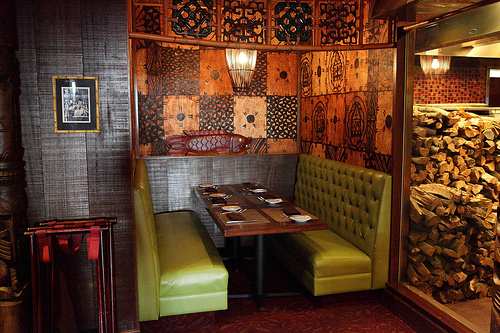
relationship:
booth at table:
[127, 154, 392, 321] [194, 181, 327, 313]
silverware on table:
[216, 214, 251, 224] [194, 181, 327, 313]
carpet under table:
[143, 293, 444, 331] [194, 181, 327, 313]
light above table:
[226, 46, 258, 93] [190, 182, 330, 313]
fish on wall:
[165, 129, 252, 157] [134, 4, 312, 153]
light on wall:
[226, 46, 258, 93] [138, 0, 301, 156]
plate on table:
[289, 212, 311, 222] [190, 182, 330, 313]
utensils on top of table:
[227, 219, 250, 228] [194, 181, 327, 313]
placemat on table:
[238, 206, 268, 229] [194, 181, 327, 313]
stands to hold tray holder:
[85, 222, 103, 260] [24, 216, 116, 332]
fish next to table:
[165, 129, 252, 157] [196, 182, 326, 236]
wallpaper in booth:
[132, 4, 386, 160] [193, 182, 328, 238]